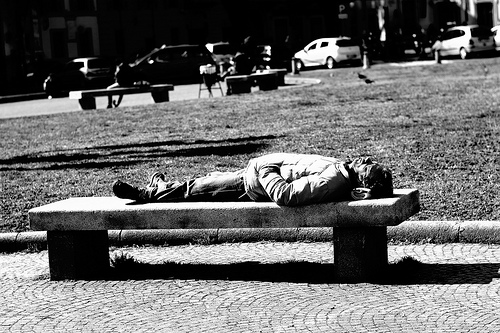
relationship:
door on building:
[77, 25, 92, 57] [0, 3, 140, 90]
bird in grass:
[361, 78, 373, 84] [4, 58, 494, 218]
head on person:
[348, 157, 382, 187] [118, 137, 400, 222]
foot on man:
[112, 180, 139, 199] [113, 153, 385, 205]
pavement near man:
[18, 290, 491, 325] [113, 153, 385, 205]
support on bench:
[49, 228, 115, 280] [27, 188, 421, 281]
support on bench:
[330, 220, 415, 277] [21, 187, 436, 297]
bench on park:
[69, 84, 174, 110] [9, 54, 497, 232]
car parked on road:
[284, 32, 366, 73] [11, 96, 53, 112]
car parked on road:
[432, 24, 495, 59] [11, 96, 53, 112]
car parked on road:
[116, 39, 220, 85] [11, 96, 53, 112]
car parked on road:
[60, 55, 102, 91] [11, 96, 53, 112]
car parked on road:
[203, 37, 237, 68] [11, 96, 53, 112]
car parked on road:
[248, 34, 278, 71] [11, 96, 53, 112]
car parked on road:
[430, 22, 496, 58] [1, 42, 485, 118]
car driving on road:
[115, 45, 216, 88] [1, 68, 316, 116]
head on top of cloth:
[349, 159, 371, 181] [351, 184, 373, 201]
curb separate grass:
[0, 220, 498, 254] [4, 58, 494, 218]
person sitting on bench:
[219, 52, 256, 96] [67, 82, 172, 110]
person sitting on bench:
[106, 52, 131, 108] [222, 68, 281, 89]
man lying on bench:
[111, 151, 390, 208] [31, 157, 437, 244]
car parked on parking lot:
[292, 36, 362, 70] [71, 29, 483, 83]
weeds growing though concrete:
[111, 251, 182, 278] [0, 240, 500, 331]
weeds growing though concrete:
[388, 252, 423, 272] [0, 240, 500, 331]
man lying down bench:
[113, 153, 385, 205] [27, 188, 421, 281]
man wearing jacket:
[113, 153, 385, 205] [238, 149, 394, 202]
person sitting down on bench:
[221, 41, 256, 85] [229, 62, 284, 97]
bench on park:
[27, 190, 422, 280] [2, 62, 495, 330]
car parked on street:
[432, 24, 495, 59] [3, 55, 498, 110]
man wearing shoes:
[113, 153, 385, 205] [110, 163, 170, 202]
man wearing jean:
[113, 153, 385, 205] [139, 166, 249, 200]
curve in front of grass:
[1, 218, 498, 251] [51, 60, 452, 166]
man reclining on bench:
[113, 153, 385, 205] [51, 205, 436, 237]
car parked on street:
[292, 36, 362, 70] [3, 55, 498, 110]